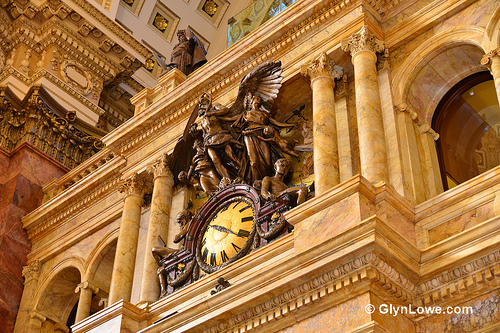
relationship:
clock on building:
[196, 194, 258, 272] [0, 0, 500, 333]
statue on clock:
[149, 60, 309, 298] [196, 194, 258, 272]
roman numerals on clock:
[201, 201, 255, 266] [196, 194, 258, 272]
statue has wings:
[166, 60, 285, 178] [170, 62, 285, 186]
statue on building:
[149, 60, 309, 298] [0, 0, 500, 333]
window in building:
[431, 71, 499, 190] [0, 0, 500, 333]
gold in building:
[1, 0, 500, 330] [0, 0, 500, 333]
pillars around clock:
[72, 51, 499, 324] [196, 194, 258, 272]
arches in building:
[32, 9, 500, 331] [0, 0, 500, 333]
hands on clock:
[204, 223, 245, 240] [196, 194, 258, 272]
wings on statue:
[170, 62, 285, 186] [166, 60, 285, 178]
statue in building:
[149, 60, 309, 298] [0, 0, 500, 333]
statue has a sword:
[166, 60, 285, 178] [183, 91, 213, 144]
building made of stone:
[0, 0, 500, 333] [1, 0, 500, 332]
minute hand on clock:
[208, 222, 222, 232] [196, 194, 258, 272]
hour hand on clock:
[219, 223, 244, 241] [196, 194, 258, 272]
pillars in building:
[72, 51, 499, 324] [0, 0, 500, 333]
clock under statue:
[196, 194, 258, 272] [149, 60, 309, 298]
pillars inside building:
[72, 51, 499, 324] [0, 0, 500, 333]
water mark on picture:
[366, 302, 475, 317] [1, 0, 500, 332]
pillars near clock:
[72, 51, 499, 324] [196, 194, 258, 272]